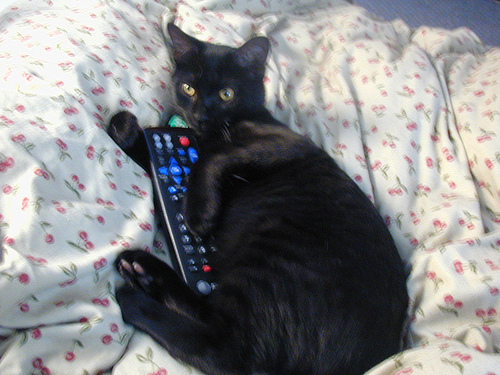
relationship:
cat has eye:
[105, 22, 418, 374] [217, 87, 236, 103]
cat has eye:
[105, 22, 418, 374] [180, 80, 196, 97]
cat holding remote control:
[105, 22, 418, 374] [138, 116, 226, 304]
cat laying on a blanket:
[105, 22, 418, 374] [2, 1, 498, 372]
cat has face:
[105, 22, 418, 374] [169, 62, 239, 138]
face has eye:
[169, 62, 239, 138] [217, 87, 236, 103]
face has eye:
[169, 62, 239, 138] [180, 80, 196, 97]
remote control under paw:
[138, 116, 226, 304] [180, 178, 220, 239]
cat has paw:
[105, 22, 418, 374] [180, 178, 220, 239]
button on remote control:
[179, 136, 192, 147] [138, 116, 226, 304]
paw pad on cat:
[134, 262, 142, 275] [105, 22, 418, 374]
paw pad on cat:
[122, 259, 134, 275] [105, 22, 418, 374]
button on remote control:
[177, 147, 187, 159] [138, 116, 226, 304]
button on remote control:
[188, 147, 199, 166] [138, 116, 226, 304]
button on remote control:
[169, 165, 183, 179] [138, 116, 226, 304]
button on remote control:
[159, 166, 171, 174] [138, 116, 226, 304]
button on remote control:
[168, 186, 178, 196] [138, 116, 226, 304]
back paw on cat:
[113, 281, 152, 334] [105, 22, 418, 374]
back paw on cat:
[113, 250, 167, 294] [105, 22, 418, 374]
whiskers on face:
[162, 99, 188, 120] [169, 62, 239, 138]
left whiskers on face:
[220, 119, 233, 144] [169, 62, 239, 138]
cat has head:
[105, 22, 418, 374] [159, 19, 276, 143]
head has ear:
[159, 19, 276, 143] [235, 33, 276, 77]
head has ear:
[159, 19, 276, 143] [166, 22, 199, 57]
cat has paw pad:
[105, 22, 418, 374] [134, 262, 142, 275]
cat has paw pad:
[105, 22, 418, 374] [122, 259, 134, 275]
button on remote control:
[196, 279, 218, 299] [138, 116, 226, 304]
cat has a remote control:
[105, 22, 418, 374] [138, 116, 226, 304]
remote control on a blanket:
[138, 116, 226, 304] [2, 1, 498, 372]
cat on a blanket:
[105, 22, 418, 374] [2, 1, 498, 372]